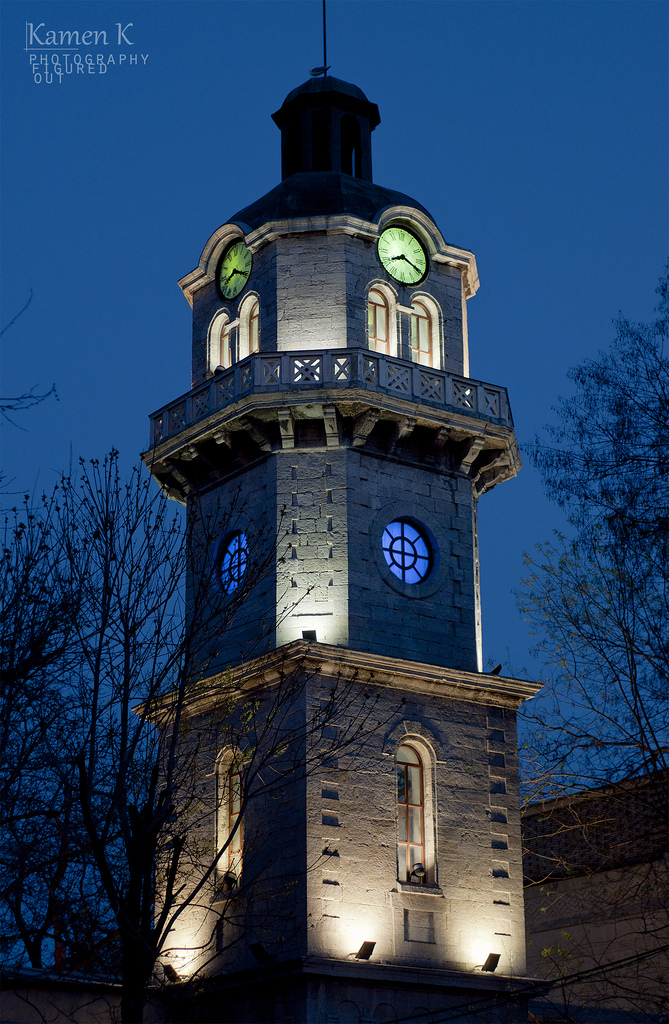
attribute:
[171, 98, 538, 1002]
building — SIDE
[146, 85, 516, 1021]
building — SIDE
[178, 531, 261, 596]
window — BLUE, CIRCULAR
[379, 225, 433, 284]
face — CLOCK, ANALOG, GREEN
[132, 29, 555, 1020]
tower — TOP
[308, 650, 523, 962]
wall — DUAL, LIT, RECTANGULAR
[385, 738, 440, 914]
window — SMALL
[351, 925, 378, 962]
light — ROUND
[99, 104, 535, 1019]
tower — CLOCK, STORY, MULTI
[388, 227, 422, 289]
face — GREEN, CLOCK